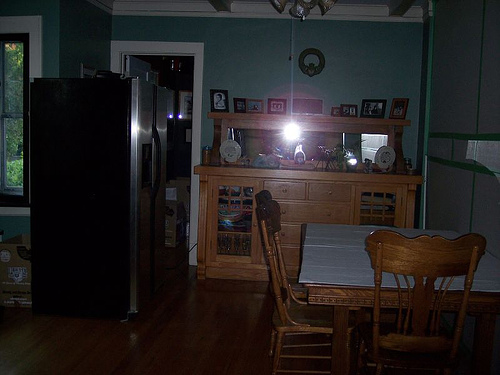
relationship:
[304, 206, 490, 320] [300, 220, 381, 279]
table has cloth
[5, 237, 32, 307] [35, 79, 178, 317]
box behind refrigerator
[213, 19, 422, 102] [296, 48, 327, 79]
wall has wreath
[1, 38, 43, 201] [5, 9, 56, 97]
window on wall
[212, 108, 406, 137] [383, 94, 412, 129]
shelf has picture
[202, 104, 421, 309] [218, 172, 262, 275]
hutch has door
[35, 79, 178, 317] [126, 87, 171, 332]
refrigerator has doors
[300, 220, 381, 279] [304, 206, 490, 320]
cloth on table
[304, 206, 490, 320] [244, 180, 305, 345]
table next chairs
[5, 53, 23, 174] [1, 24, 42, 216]
trees behind window